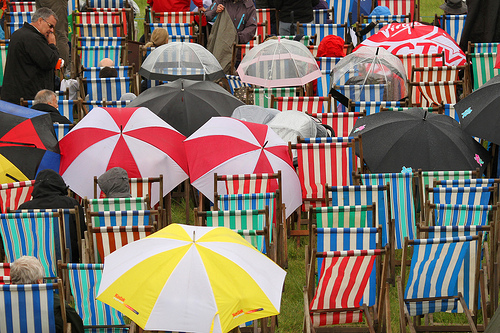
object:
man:
[0, 7, 63, 105]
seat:
[323, 180, 395, 287]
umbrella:
[95, 221, 288, 333]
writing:
[113, 293, 141, 315]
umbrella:
[348, 107, 493, 185]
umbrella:
[236, 35, 323, 89]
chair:
[287, 141, 355, 249]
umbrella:
[58, 106, 190, 210]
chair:
[396, 230, 489, 333]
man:
[10, 255, 86, 333]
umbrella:
[137, 41, 228, 81]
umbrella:
[332, 45, 408, 101]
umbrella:
[181, 115, 303, 221]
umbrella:
[350, 21, 473, 68]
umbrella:
[0, 100, 61, 153]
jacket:
[0, 21, 62, 104]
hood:
[316, 34, 346, 57]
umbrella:
[123, 77, 247, 138]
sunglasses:
[41, 16, 55, 29]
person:
[86, 167, 157, 221]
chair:
[0, 207, 70, 295]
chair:
[307, 200, 377, 227]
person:
[30, 89, 74, 124]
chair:
[0, 277, 70, 333]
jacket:
[18, 168, 88, 265]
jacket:
[202, 0, 258, 45]